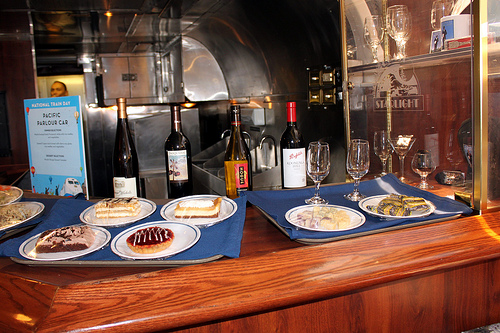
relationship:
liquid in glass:
[347, 160, 370, 177] [343, 139, 370, 202]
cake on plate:
[78, 177, 225, 288] [79, 197, 155, 227]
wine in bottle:
[108, 99, 140, 198] [111, 97, 143, 195]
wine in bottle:
[165, 103, 190, 199] [167, 100, 191, 196]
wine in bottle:
[223, 100, 251, 199] [224, 101, 248, 193]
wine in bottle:
[280, 100, 308, 189] [279, 100, 307, 187]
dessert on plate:
[174, 193, 231, 228] [156, 188, 238, 228]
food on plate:
[293, 207, 353, 230] [284, 202, 370, 234]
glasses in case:
[355, 4, 453, 68] [341, 0, 499, 211]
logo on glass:
[374, 56, 423, 113] [330, 17, 493, 184]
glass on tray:
[374, 130, 394, 177] [243, 175, 468, 246]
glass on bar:
[408, 147, 436, 188] [1, 189, 499, 331]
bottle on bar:
[281, 103, 308, 191] [1, 189, 499, 331]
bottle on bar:
[227, 105, 250, 194] [1, 189, 499, 331]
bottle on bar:
[166, 104, 194, 194] [1, 189, 499, 331]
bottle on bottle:
[112, 95, 139, 197] [281, 103, 308, 191]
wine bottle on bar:
[226, 97, 253, 201] [1, 189, 499, 331]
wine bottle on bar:
[282, 100, 310, 187] [1, 189, 499, 331]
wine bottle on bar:
[161, 100, 199, 196] [1, 189, 499, 331]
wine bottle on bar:
[113, 100, 143, 183] [1, 189, 499, 331]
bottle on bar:
[112, 95, 139, 197] [1, 189, 499, 331]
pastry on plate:
[179, 180, 219, 217] [156, 188, 238, 228]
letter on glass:
[374, 97, 381, 109] [348, 67, 472, 137]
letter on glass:
[374, 97, 386, 108] [434, 74, 454, 120]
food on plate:
[34, 225, 94, 254] [17, 223, 111, 262]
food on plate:
[176, 197, 223, 217] [158, 192, 239, 227]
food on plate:
[376, 195, 424, 217] [221, 200, 233, 217]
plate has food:
[109, 215, 201, 263] [127, 222, 174, 254]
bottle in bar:
[222, 102, 254, 198] [1, 189, 499, 331]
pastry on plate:
[129, 223, 178, 258] [115, 221, 210, 260]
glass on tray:
[299, 140, 330, 207] [243, 175, 468, 246]